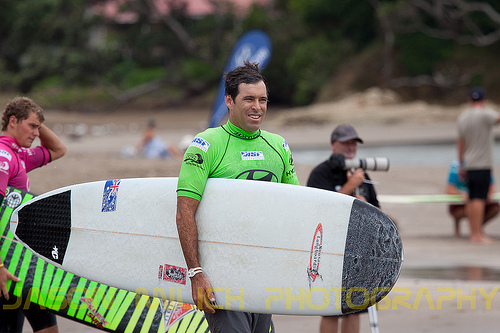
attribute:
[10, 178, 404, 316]
surfboard — white , black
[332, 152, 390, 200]
camera — long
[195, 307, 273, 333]
shorts — gray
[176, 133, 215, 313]
arm — carrying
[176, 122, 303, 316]
shirt — green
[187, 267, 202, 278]
watch — white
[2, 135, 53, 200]
shirt — pink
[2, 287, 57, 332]
shorts — black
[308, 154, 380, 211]
shirt — black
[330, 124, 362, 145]
cap — brown, grey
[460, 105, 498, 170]
shirt — tan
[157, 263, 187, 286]
symbol — red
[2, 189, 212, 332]
surfboard — green, black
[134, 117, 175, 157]
person — sitting